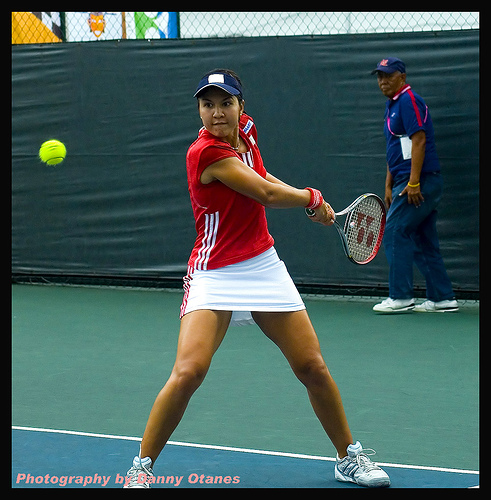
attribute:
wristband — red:
[306, 185, 322, 208]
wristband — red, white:
[312, 184, 322, 214]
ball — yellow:
[25, 123, 88, 180]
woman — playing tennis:
[163, 65, 366, 495]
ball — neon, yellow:
[34, 133, 70, 171]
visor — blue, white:
[176, 57, 253, 115]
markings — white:
[11, 422, 478, 487]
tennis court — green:
[10, 277, 479, 486]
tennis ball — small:
[38, 136, 68, 166]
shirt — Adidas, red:
[184, 129, 298, 265]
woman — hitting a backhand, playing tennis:
[106, 58, 399, 488]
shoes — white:
[366, 294, 462, 319]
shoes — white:
[119, 451, 161, 493]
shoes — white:
[323, 441, 394, 489]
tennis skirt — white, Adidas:
[177, 244, 306, 324]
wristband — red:
[302, 186, 316, 209]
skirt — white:
[179, 238, 303, 320]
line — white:
[10, 425, 479, 474]